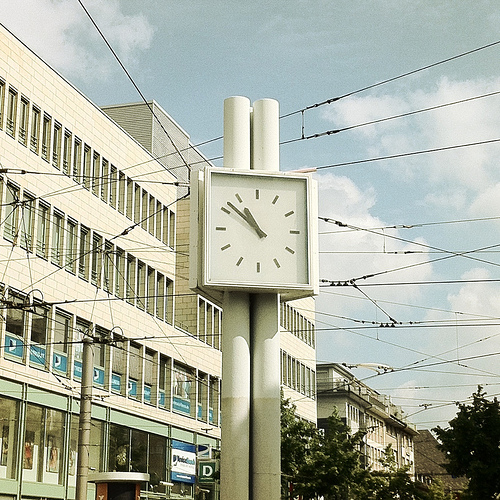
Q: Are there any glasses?
A: No, there are no glasses.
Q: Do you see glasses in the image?
A: No, there are no glasses.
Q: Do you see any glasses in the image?
A: No, there are no glasses.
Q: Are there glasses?
A: No, there are no glasses.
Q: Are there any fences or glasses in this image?
A: No, there are no glasses or fences.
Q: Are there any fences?
A: No, there are no fences.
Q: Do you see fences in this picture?
A: No, there are no fences.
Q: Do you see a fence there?
A: No, there are no fences.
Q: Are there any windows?
A: Yes, there is a window.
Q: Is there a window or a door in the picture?
A: Yes, there is a window.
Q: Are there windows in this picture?
A: Yes, there is a window.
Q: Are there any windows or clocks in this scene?
A: Yes, there is a window.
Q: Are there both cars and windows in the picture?
A: No, there is a window but no cars.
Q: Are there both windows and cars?
A: No, there is a window but no cars.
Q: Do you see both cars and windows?
A: No, there is a window but no cars.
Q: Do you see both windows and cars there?
A: No, there is a window but no cars.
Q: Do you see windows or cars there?
A: Yes, there is a window.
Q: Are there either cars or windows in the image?
A: Yes, there is a window.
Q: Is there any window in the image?
A: Yes, there is a window.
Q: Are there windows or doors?
A: Yes, there is a window.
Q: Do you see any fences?
A: No, there are no fences.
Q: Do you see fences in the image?
A: No, there are no fences.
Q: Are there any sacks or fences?
A: No, there are no fences or sacks.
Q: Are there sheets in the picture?
A: No, there are no sheets.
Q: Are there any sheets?
A: No, there are no sheets.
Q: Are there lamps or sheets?
A: No, there are no sheets or lamps.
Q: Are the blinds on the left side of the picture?
A: Yes, the blinds are on the left of the image.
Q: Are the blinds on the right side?
A: No, the blinds are on the left of the image.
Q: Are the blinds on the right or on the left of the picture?
A: The blinds are on the left of the image.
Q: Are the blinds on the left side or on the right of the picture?
A: The blinds are on the left of the image.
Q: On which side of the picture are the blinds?
A: The blinds are on the left of the image.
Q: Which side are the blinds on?
A: The blinds are on the left of the image.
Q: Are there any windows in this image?
A: Yes, there are windows.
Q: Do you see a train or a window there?
A: Yes, there are windows.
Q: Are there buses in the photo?
A: No, there are no buses.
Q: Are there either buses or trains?
A: No, there are no buses or trains.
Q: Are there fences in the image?
A: No, there are no fences.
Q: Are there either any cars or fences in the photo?
A: No, there are no fences or cars.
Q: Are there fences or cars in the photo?
A: No, there are no fences or cars.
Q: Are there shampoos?
A: No, there are no shampoos.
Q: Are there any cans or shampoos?
A: No, there are no shampoos or cans.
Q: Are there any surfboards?
A: No, there are no surfboards.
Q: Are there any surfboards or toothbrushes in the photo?
A: No, there are no surfboards or toothbrushes.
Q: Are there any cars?
A: No, there are no cars.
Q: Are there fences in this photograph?
A: No, there are no fences.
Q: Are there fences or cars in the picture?
A: No, there are no fences or cars.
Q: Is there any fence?
A: No, there are no fences.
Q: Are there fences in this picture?
A: No, there are no fences.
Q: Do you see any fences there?
A: No, there are no fences.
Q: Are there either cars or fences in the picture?
A: No, there are no fences or cars.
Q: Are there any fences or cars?
A: No, there are no fences or cars.